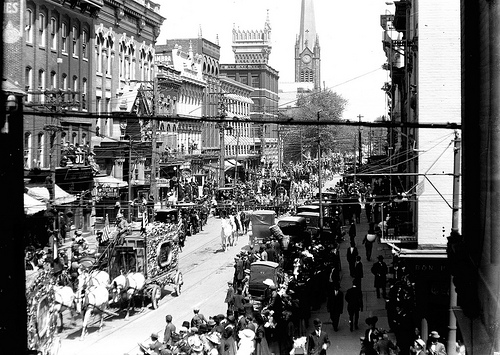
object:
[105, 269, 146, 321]
horse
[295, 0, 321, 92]
tower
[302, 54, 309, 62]
clock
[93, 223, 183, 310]
carriage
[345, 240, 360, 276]
person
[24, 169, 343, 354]
road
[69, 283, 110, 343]
horse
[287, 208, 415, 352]
person street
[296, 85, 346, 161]
tree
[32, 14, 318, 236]
buildings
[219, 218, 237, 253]
horse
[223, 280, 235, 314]
person